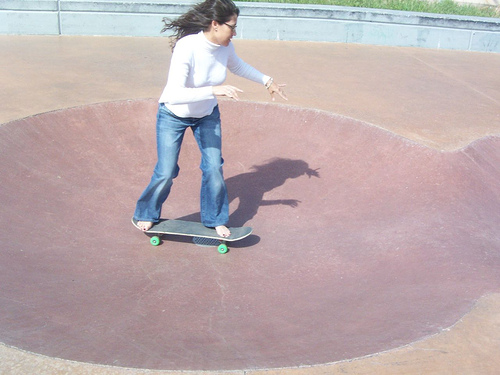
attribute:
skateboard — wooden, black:
[131, 217, 253, 254]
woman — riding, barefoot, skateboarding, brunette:
[133, 0, 288, 237]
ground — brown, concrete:
[0, 34, 499, 375]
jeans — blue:
[133, 104, 229, 229]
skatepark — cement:
[1, 1, 499, 374]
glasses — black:
[223, 22, 236, 32]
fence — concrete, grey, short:
[0, 0, 499, 53]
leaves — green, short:
[236, 0, 496, 19]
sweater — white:
[158, 30, 271, 118]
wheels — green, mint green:
[150, 236, 227, 254]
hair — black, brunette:
[160, 0, 240, 52]